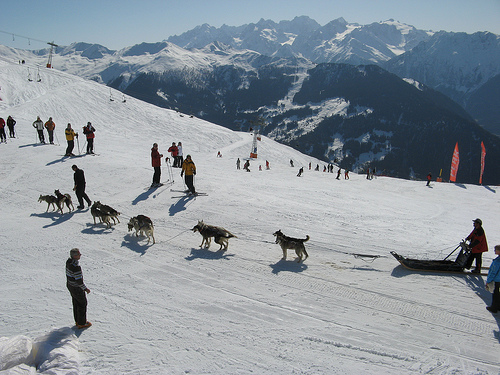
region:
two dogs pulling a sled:
[270, 225, 315, 267]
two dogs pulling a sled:
[191, 214, 234, 255]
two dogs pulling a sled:
[123, 210, 165, 248]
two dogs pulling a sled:
[90, 198, 120, 228]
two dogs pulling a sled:
[32, 185, 74, 222]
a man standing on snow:
[58, 242, 113, 341]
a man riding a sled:
[387, 212, 487, 282]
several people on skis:
[3, 110, 104, 162]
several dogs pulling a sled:
[36, 187, 498, 259]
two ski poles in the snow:
[161, 153, 177, 190]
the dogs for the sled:
[32, 186, 317, 279]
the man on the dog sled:
[381, 211, 493, 283]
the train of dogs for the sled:
[30, 182, 497, 282]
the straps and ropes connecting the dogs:
[269, 222, 393, 273]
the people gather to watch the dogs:
[3, 113, 113, 157]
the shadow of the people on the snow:
[123, 188, 202, 216]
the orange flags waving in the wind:
[441, 136, 493, 193]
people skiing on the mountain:
[229, 148, 386, 188]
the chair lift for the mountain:
[5, 24, 60, 68]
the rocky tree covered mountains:
[313, 64, 443, 159]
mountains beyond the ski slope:
[171, 15, 361, 97]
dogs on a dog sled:
[40, 186, 316, 254]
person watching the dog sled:
[54, 243, 115, 347]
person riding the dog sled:
[454, 215, 487, 266]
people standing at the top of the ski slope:
[31, 108, 102, 154]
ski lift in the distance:
[4, 28, 68, 68]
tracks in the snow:
[236, 282, 371, 342]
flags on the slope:
[448, 131, 488, 187]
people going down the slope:
[237, 143, 367, 188]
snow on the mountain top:
[134, 37, 184, 62]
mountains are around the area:
[41, 19, 498, 186]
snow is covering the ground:
[5, 55, 495, 373]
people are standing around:
[1, 100, 497, 359]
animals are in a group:
[36, 183, 319, 271]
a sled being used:
[392, 238, 478, 270]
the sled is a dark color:
[391, 243, 477, 270]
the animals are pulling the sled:
[30, 182, 468, 302]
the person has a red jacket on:
[465, 220, 486, 269]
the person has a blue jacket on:
[482, 244, 497, 312]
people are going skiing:
[143, 144, 203, 199]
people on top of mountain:
[0, 0, 499, 365]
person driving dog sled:
[34, 178, 491, 298]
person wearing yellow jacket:
[176, 154, 202, 182]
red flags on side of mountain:
[380, 114, 495, 206]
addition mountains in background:
[2, 3, 496, 220]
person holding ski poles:
[50, 118, 86, 170]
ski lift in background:
[2, 15, 173, 120]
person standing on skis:
[163, 140, 213, 210]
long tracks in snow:
[100, 247, 480, 369]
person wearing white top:
[27, 115, 52, 136]